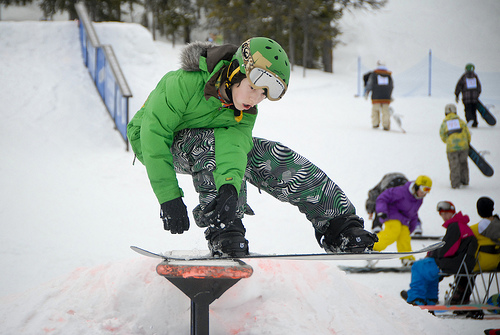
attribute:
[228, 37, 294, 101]
helmet — green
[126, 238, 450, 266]
snowboard — grey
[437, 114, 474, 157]
jacket — green, yellow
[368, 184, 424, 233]
jacket — purple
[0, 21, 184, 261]
hill — snowy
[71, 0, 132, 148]
ramp — blue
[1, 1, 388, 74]
trees — green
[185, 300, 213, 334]
post — black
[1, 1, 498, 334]
snow — white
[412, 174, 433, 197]
helmet — yellow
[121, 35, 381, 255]
snowboarder — snowboarding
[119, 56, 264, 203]
jacket — green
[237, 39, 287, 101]
goggles — brown, white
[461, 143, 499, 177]
snowboard — black, blue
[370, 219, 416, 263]
snowpants — yellow, khaki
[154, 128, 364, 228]
snowpants — designed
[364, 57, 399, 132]
snowboarder — walking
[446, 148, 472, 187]
snowpants — camouflage design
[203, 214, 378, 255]
boots — black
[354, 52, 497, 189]
hill — snowy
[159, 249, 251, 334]
rail — black, orange